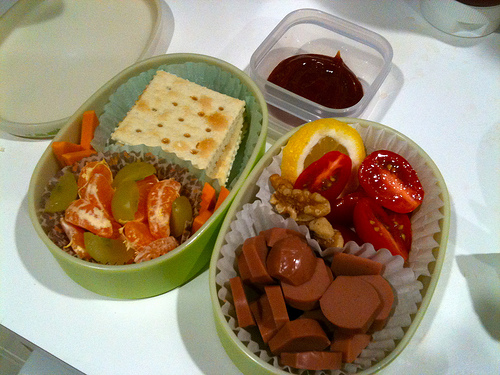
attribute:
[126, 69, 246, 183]
crackers — stacked, white, brown, is oval shaped, is square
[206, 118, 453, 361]
cup — filled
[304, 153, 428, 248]
tomatoes — red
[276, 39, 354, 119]
ketchup — red, small, dark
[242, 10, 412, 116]
container — white, clear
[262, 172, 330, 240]
nuts — brown, small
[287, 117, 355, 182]
lemon — yellow, cut, small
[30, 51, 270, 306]
bowl — is green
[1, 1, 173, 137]
lid — is oval shaped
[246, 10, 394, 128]
container — is small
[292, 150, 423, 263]
tomatoes — cut, are cherry-flavored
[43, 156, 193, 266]
grapes — are seedless, are green, cut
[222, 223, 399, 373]
hot dogs — are cut, are sliced